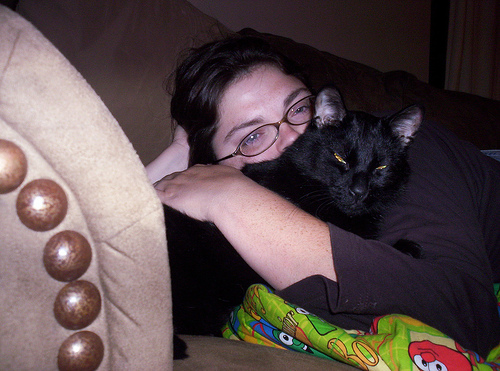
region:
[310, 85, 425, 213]
the face of a black cat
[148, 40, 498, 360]
a woman holding a black cat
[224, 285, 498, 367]
a veggie tales blanket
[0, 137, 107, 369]
metal rivets on a couch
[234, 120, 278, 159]
right eye of a woman with glasses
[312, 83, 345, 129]
right ear of a cat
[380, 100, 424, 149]
left ear of a cat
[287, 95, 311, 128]
the left eye of a woman with glasses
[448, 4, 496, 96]
white fabric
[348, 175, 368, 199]
the nose of a black cat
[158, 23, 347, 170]
The girl has dark hair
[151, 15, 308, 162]
The girl's hair is black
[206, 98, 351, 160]
The girl is wearing corrective lenses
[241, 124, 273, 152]
The girl has a blue eye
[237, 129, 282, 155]
The girl's eye is open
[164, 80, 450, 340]
The girl is holding a cat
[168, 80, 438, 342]
The cat is almost asleep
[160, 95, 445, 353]
The black cat is resting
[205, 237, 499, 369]
The blanket is green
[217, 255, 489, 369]
The blanket has Angry Birds on it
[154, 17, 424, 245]
woman wearing glasses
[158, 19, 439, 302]
woman laying with black cat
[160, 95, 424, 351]
a black cat resting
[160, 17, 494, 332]
woman wearing a black shirt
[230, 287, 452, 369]
colorful characters on blanket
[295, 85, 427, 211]
a black cat with ears pointed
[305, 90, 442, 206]
black cat with yellow eyes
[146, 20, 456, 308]
woman with arm around cat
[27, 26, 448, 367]
woman and cat on couch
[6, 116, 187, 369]
decorative buttons on couch arm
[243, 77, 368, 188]
The woman has glasses on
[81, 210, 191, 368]
The couch is light colored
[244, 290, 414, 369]
The blanket is colorful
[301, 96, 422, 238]
The cat is black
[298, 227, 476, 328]
The lady has a long sleeve shirt on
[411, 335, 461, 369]
The character on the blanket has 2 eyes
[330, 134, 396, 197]
The cat is squinting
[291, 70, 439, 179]
The cat has 2 ears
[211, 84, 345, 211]
The cat is by the woman's face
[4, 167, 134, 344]
The decorations are gold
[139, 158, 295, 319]
woman's arm around cat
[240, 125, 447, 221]
cat is black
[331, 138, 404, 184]
cat's eyes look yellow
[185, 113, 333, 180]
woman is wearing glasses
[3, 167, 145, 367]
wooden buttons on the sofa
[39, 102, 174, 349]
sofa is tan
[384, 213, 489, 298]
woman's shirt is black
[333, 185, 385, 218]
cat's nose is black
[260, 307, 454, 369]
cartoons on the blanket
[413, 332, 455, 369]
cartoon on the blanket is red